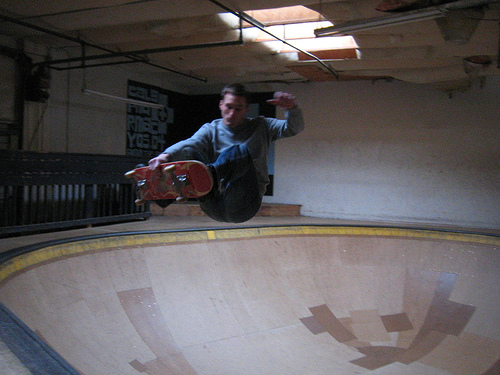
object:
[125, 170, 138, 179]
wheel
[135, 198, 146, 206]
wheel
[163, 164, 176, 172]
wheel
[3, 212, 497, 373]
court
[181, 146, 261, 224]
jeans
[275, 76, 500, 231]
brick wall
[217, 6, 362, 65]
light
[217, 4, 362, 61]
window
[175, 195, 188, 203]
wheel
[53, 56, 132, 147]
wall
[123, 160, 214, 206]
red skateboard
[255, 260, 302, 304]
white structure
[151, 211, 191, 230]
ground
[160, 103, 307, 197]
sweater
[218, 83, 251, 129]
head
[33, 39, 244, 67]
pipes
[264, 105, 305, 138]
arm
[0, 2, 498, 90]
ceiling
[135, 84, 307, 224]
man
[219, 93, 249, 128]
face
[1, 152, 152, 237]
rail